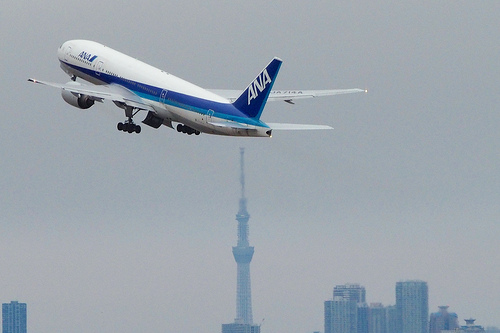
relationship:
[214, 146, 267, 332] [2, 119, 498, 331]
tower in distance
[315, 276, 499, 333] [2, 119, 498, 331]
buildings in distance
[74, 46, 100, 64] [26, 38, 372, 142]
logo on plane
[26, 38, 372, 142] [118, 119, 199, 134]
plane has wheels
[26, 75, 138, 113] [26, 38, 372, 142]
wing of plane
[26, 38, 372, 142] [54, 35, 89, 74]
plane has front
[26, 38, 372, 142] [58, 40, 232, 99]
plane has top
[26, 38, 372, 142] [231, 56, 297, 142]
plane has tail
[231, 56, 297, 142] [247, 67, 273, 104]
tail says ana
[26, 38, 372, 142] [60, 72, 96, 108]
plane has engine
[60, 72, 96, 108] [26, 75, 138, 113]
engine on wing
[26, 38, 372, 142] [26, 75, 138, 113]
plane has wing